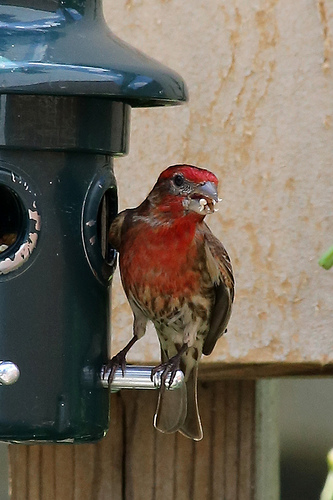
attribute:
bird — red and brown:
[108, 165, 237, 451]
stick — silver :
[103, 363, 185, 390]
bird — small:
[97, 160, 239, 444]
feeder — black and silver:
[1, 0, 188, 445]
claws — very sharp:
[148, 343, 187, 395]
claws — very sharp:
[100, 337, 135, 388]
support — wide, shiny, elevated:
[99, 363, 187, 393]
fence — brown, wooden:
[9, 375, 255, 498]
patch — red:
[121, 216, 197, 303]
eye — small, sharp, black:
[169, 172, 188, 190]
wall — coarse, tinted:
[103, 1, 322, 367]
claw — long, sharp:
[97, 336, 135, 393]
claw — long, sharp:
[146, 345, 188, 391]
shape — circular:
[1, 160, 46, 281]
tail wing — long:
[153, 340, 205, 441]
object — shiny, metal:
[99, 363, 184, 393]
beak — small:
[185, 179, 218, 215]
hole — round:
[94, 184, 118, 265]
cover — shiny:
[1, 0, 190, 108]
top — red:
[157, 162, 219, 186]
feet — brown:
[107, 334, 189, 383]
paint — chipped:
[2, 205, 39, 284]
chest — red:
[124, 214, 204, 300]